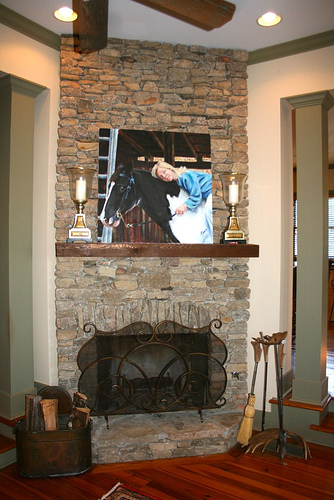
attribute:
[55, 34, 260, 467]
fireplace — stone, gray, rock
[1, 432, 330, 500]
floor — wooden, red wood, hardwood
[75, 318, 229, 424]
cover — screen, ornate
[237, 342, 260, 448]
broom — little, brown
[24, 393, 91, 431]
logs — sticks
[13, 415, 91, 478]
container — old, brass, copper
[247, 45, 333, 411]
wall — white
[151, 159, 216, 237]
woman — resting, in blue, blonde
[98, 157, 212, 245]
horse — black, white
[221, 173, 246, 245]
candleholder — large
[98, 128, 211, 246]
picture — large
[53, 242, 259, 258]
mantle — wood, brown, a beam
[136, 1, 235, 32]
blade — brown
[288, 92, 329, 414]
column — green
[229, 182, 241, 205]
candle — white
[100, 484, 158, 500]
rug — ornate